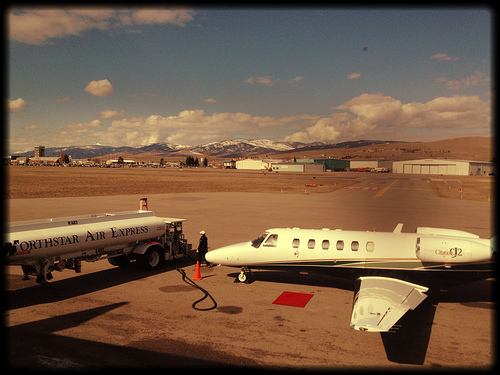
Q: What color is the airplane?
A: White.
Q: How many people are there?
A: 1.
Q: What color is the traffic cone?
A: Orange.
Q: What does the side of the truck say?
A: Northstar Air Express.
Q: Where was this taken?
A: Airport.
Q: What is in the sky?
A: Clouds.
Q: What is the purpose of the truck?
A: Fuel the plane.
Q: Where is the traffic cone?
A: In front of the plane.